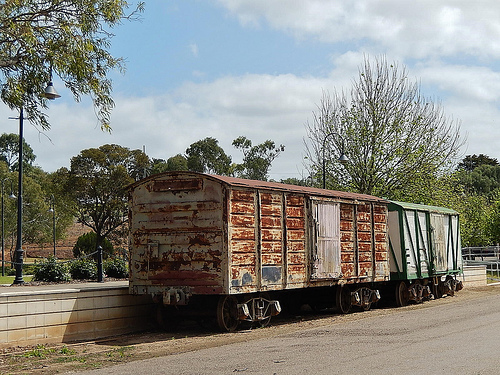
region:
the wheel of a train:
[211, 295, 238, 334]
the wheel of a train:
[331, 287, 354, 321]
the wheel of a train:
[390, 277, 409, 300]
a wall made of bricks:
[1, 285, 137, 347]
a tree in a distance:
[70, 145, 145, 261]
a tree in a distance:
[305, 48, 440, 201]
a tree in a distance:
[451, 142, 499, 214]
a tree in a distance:
[3, 5, 125, 138]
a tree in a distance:
[1, 132, 34, 159]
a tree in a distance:
[0, 162, 45, 262]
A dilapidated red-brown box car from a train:
[124, 175, 391, 283]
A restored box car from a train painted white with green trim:
[387, 202, 461, 283]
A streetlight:
[17, 50, 59, 280]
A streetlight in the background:
[320, 132, 348, 186]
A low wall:
[0, 280, 132, 340]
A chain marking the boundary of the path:
[1, 242, 130, 280]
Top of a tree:
[310, 62, 455, 195]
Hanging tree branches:
[0, 2, 149, 134]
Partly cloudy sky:
[2, 0, 498, 164]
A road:
[68, 290, 498, 373]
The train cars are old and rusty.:
[136, 169, 491, 303]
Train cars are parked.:
[125, 168, 497, 293]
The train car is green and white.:
[389, 186, 463, 290]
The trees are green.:
[28, 111, 130, 278]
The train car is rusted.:
[121, 163, 395, 318]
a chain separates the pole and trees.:
[1, 237, 126, 280]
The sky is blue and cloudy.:
[206, 20, 486, 70]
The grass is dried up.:
[13, 335, 139, 369]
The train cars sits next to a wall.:
[8, 184, 470, 352]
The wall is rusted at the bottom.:
[3, 288, 148, 336]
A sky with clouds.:
[17, 0, 493, 170]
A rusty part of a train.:
[105, 150, 475, 335]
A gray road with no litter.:
[90, 275, 495, 365]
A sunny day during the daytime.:
[6, 6, 496, 326]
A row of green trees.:
[10, 82, 496, 298]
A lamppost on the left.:
[6, 56, 72, 311]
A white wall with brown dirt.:
[0, 270, 210, 345]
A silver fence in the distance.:
[437, 235, 497, 272]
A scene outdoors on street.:
[11, 2, 491, 372]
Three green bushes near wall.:
[29, 246, 159, 297]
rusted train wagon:
[125, 169, 390, 329]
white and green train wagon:
[385, 200, 465, 308]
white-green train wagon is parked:
[391, 200, 463, 308]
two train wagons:
[126, 168, 465, 335]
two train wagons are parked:
[126, 169, 466, 331]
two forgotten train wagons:
[126, 168, 464, 329]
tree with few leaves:
[316, 53, 471, 198]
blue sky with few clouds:
[144, 1, 374, 130]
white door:
[307, 193, 343, 283]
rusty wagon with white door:
[124, 168, 390, 324]